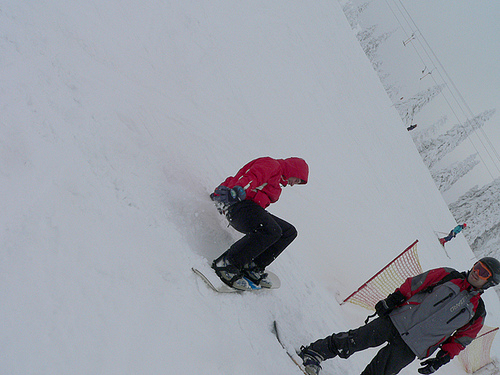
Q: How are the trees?
A: Covered with snow.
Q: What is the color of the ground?
A: White.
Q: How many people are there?
A: 3.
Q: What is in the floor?
A: Snow.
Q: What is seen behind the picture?
A: Trees.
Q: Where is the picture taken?
A: In the snow.